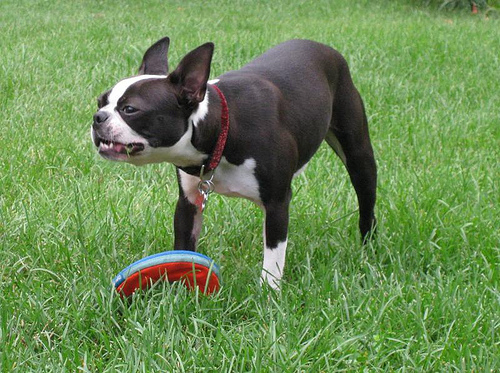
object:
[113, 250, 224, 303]
frisbee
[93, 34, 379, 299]
dog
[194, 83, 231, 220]
collar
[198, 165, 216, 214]
tag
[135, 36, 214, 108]
ears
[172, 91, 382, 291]
legs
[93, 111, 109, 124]
nose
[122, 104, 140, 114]
eyes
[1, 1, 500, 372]
grass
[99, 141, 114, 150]
teeth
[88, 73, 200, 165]
head